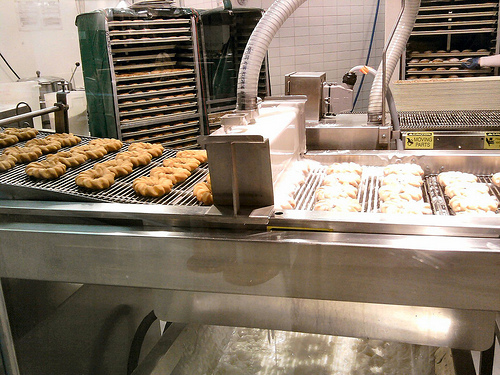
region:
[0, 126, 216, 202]
Several donuts on the left of the conveyer belt.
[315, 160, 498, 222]
Three rows of uncooked donuts on the conveyer.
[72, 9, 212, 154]
Green movable donut cart with multiple racks on it.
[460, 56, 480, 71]
A hand with a black glove on it.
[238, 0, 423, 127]
A large tube going from one side of the belt to another.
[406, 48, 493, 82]
Four racks of donuts beside a persons hand.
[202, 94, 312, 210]
Large metal rectangular section of a conveyer belt that heats the donuts.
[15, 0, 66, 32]
Two signs on the back wall.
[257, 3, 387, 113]
White tiles on the wall.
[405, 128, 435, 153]
Warning label to the right of a conveyer belt.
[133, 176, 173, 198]
doughnut on a conveyor belt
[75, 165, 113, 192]
doughnut next to doughnut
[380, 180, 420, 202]
doughnut covered with powdered sugar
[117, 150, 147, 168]
a plain doughnut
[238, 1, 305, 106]
flexible plastic tube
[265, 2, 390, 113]
white tile wall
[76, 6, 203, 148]
tall rack for trays of doughnuts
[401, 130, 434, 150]
yellow sticker on conveyor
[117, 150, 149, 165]
doughnut is fresh and warm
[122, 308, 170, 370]
black hose under conveyor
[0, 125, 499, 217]
donuts on a conveyor belt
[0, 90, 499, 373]
a metal conveyor belt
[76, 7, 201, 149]
stacked trays of donuts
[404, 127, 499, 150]
warning stickers on the machines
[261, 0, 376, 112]
white tiles on the wall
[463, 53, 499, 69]
a worker's arm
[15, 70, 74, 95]
a metal container in the back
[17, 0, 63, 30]
signs on the wall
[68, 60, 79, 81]
a metal handle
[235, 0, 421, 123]
hoses connected to the machine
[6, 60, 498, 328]
this machine is icing the crullers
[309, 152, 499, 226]
these crullers are ready to be sold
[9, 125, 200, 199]
these crullers do not have icing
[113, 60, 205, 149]
donuts are stored in these pans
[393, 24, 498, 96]
finished donuts are placed in these pans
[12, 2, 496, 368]
this looks like the inside of a Krispy Kreme Donuts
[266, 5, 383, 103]
the wall is made of white tile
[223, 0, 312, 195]
the glaze comes through this pipe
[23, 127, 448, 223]
these little rollers keep the crullers moving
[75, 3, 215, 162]
the rack has a green cover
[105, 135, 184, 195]
doughnuts on conveyor belt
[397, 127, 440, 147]
yellow sticker with black writing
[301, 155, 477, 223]
lines of doughnuts on factory equipment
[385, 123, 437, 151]
sign that says moving parts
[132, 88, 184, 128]
doughnuts drying on racks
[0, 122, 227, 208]
six lines of doughnuts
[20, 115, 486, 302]
metal conveyor belt with doughnuts on it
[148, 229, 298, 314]
reflection on silver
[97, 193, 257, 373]
black hose under silver conveyor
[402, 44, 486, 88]
doughnuts with white frosting